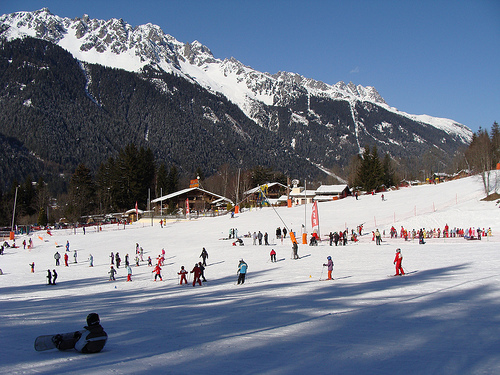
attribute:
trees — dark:
[465, 122, 496, 174]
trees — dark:
[356, 144, 395, 189]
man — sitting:
[52, 311, 108, 355]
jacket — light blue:
[237, 265, 249, 275]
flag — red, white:
[306, 195, 326, 240]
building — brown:
[148, 174, 229, 219]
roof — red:
[157, 181, 189, 201]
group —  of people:
[20, 220, 491, 290]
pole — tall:
[11, 184, 19, 235]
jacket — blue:
[237, 261, 246, 275]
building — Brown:
[313, 181, 349, 202]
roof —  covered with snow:
[314, 183, 350, 193]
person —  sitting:
[373, 223, 465, 332]